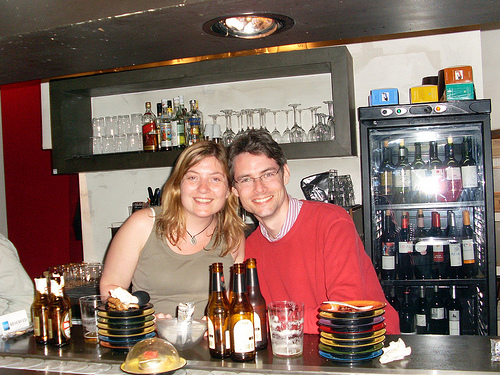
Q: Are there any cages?
A: No, there are no cages.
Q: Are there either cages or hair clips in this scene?
A: No, there are no cages or hair clips.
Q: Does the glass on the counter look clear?
A: Yes, the glass is clear.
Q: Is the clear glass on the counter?
A: Yes, the glass is on the counter.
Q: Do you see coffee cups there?
A: No, there are no coffee cups.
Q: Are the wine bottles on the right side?
A: Yes, the wine bottles are on the right of the image.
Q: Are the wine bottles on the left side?
A: No, the wine bottles are on the right of the image.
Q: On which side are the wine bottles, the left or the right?
A: The wine bottles are on the right of the image.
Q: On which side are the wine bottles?
A: The wine bottles are on the right of the image.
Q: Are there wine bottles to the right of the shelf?
A: Yes, there are wine bottles to the right of the shelf.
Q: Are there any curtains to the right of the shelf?
A: No, there are wine bottles to the right of the shelf.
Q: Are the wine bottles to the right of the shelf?
A: Yes, the wine bottles are to the right of the shelf.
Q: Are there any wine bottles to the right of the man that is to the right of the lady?
A: Yes, there are wine bottles to the right of the man.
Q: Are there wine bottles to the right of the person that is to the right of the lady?
A: Yes, there are wine bottles to the right of the man.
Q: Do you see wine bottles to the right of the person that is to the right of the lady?
A: Yes, there are wine bottles to the right of the man.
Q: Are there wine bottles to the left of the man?
A: No, the wine bottles are to the right of the man.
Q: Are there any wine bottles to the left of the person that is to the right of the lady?
A: No, the wine bottles are to the right of the man.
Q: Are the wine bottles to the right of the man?
A: Yes, the wine bottles are to the right of the man.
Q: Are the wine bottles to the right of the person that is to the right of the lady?
A: Yes, the wine bottles are to the right of the man.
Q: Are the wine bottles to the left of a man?
A: No, the wine bottles are to the right of a man.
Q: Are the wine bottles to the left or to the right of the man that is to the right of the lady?
A: The wine bottles are to the right of the man.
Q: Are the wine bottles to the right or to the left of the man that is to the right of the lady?
A: The wine bottles are to the right of the man.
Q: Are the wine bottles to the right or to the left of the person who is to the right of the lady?
A: The wine bottles are to the right of the man.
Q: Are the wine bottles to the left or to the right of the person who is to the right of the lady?
A: The wine bottles are to the right of the man.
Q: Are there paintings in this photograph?
A: No, there are no paintings.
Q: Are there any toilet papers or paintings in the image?
A: No, there are no paintings or toilet papers.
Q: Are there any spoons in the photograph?
A: Yes, there is a spoon.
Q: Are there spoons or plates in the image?
A: Yes, there is a spoon.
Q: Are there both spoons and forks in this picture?
A: No, there is a spoon but no forks.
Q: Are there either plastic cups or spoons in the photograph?
A: Yes, there is a plastic spoon.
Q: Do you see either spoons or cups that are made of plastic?
A: Yes, the spoon is made of plastic.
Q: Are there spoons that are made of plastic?
A: Yes, there is a spoon that is made of plastic.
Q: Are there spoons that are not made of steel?
A: Yes, there is a spoon that is made of plastic.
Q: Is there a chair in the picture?
A: No, there are no chairs.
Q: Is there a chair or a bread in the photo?
A: No, there are no chairs or breads.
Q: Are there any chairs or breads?
A: No, there are no chairs or breads.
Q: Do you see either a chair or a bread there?
A: No, there are no chairs or breads.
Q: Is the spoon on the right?
A: Yes, the spoon is on the right of the image.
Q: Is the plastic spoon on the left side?
A: No, the spoon is on the right of the image.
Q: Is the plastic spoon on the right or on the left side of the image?
A: The spoon is on the right of the image.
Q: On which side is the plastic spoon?
A: The spoon is on the right of the image.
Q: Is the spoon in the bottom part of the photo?
A: Yes, the spoon is in the bottom of the image.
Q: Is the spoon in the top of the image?
A: No, the spoon is in the bottom of the image.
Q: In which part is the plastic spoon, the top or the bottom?
A: The spoon is in the bottom of the image.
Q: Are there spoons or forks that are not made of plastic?
A: No, there is a spoon but it is made of plastic.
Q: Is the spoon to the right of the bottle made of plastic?
A: Yes, the spoon is made of plastic.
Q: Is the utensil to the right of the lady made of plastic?
A: Yes, the spoon is made of plastic.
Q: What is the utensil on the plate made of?
A: The spoon is made of plastic.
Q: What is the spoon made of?
A: The spoon is made of plastic.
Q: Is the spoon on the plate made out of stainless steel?
A: No, the spoon is made of plastic.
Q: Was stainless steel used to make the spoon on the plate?
A: No, the spoon is made of plastic.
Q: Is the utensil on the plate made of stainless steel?
A: No, the spoon is made of plastic.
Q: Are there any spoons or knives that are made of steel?
A: No, there is a spoon but it is made of plastic.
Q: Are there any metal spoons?
A: No, there is a spoon but it is made of plastic.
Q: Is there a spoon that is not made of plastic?
A: No, there is a spoon but it is made of plastic.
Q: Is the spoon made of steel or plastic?
A: The spoon is made of plastic.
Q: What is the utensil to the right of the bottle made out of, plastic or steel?
A: The spoon is made of plastic.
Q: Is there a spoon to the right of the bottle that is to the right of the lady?
A: Yes, there is a spoon to the right of the bottle.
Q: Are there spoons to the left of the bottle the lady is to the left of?
A: No, the spoon is to the right of the bottle.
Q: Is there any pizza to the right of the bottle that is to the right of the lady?
A: No, there is a spoon to the right of the bottle.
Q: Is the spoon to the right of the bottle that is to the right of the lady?
A: Yes, the spoon is to the right of the bottle.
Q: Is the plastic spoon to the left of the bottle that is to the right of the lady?
A: No, the spoon is to the right of the bottle.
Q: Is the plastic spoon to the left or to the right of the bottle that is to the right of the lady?
A: The spoon is to the right of the bottle.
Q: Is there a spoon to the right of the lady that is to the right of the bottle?
A: Yes, there is a spoon to the right of the lady.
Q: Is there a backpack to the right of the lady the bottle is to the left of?
A: No, there is a spoon to the right of the lady.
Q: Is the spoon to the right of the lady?
A: Yes, the spoon is to the right of the lady.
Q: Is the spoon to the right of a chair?
A: No, the spoon is to the right of the lady.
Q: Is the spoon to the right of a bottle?
A: Yes, the spoon is to the right of a bottle.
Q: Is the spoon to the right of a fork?
A: No, the spoon is to the right of a bottle.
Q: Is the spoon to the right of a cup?
A: No, the spoon is to the right of a bottle.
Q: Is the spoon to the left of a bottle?
A: No, the spoon is to the right of a bottle.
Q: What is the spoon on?
A: The spoon is on the plate.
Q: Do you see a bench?
A: No, there are no benches.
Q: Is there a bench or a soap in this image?
A: No, there are no benches or soaps.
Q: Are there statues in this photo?
A: No, there are no statues.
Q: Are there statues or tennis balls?
A: No, there are no statues or tennis balls.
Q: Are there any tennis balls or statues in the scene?
A: No, there are no statues or tennis balls.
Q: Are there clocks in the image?
A: No, there are no clocks.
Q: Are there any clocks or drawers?
A: No, there are no clocks or drawers.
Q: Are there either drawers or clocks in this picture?
A: No, there are no clocks or drawers.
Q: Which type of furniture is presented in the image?
A: The furniture is a shelf.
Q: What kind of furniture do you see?
A: The furniture is a shelf.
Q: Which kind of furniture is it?
A: The piece of furniture is a shelf.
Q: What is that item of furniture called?
A: This is a shelf.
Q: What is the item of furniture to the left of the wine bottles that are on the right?
A: The piece of furniture is a shelf.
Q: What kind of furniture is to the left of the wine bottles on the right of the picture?
A: The piece of furniture is a shelf.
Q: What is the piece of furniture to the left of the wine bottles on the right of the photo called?
A: The piece of furniture is a shelf.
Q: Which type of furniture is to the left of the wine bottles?
A: The piece of furniture is a shelf.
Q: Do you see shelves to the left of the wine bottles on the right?
A: Yes, there is a shelf to the left of the wine bottles.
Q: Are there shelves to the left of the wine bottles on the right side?
A: Yes, there is a shelf to the left of the wine bottles.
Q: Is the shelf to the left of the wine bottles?
A: Yes, the shelf is to the left of the wine bottles.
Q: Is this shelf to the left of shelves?
A: No, the shelf is to the left of the wine bottles.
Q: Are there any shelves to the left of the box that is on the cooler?
A: Yes, there is a shelf to the left of the box.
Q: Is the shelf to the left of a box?
A: Yes, the shelf is to the left of a box.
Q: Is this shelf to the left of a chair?
A: No, the shelf is to the left of a box.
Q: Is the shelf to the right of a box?
A: No, the shelf is to the left of a box.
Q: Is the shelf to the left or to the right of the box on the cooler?
A: The shelf is to the left of the box.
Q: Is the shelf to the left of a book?
A: No, the shelf is to the left of the box.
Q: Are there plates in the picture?
A: Yes, there is a plate.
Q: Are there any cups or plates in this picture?
A: Yes, there is a plate.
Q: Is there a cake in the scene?
A: No, there are no cakes.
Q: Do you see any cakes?
A: No, there are no cakes.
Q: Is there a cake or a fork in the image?
A: No, there are no cakes or forks.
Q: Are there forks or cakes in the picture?
A: No, there are no cakes or forks.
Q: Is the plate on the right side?
A: Yes, the plate is on the right of the image.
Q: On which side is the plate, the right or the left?
A: The plate is on the right of the image.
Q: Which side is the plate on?
A: The plate is on the right of the image.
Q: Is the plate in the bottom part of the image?
A: Yes, the plate is in the bottom of the image.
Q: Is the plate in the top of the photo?
A: No, the plate is in the bottom of the image.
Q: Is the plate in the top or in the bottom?
A: The plate is in the bottom of the image.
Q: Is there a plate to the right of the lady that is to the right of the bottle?
A: Yes, there is a plate to the right of the lady.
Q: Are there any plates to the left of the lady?
A: No, the plate is to the right of the lady.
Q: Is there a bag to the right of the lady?
A: No, there is a plate to the right of the lady.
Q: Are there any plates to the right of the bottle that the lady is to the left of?
A: Yes, there is a plate to the right of the bottle.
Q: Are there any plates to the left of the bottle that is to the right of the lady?
A: No, the plate is to the right of the bottle.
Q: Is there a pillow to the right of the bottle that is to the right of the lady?
A: No, there is a plate to the right of the bottle.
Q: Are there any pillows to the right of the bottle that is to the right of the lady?
A: No, there is a plate to the right of the bottle.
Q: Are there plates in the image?
A: Yes, there is a plate.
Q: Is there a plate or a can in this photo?
A: Yes, there is a plate.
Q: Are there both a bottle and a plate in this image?
A: Yes, there are both a plate and a bottle.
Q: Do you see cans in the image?
A: No, there are no cans.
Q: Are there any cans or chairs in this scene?
A: No, there are no cans or chairs.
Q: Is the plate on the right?
A: Yes, the plate is on the right of the image.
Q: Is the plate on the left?
A: No, the plate is on the right of the image.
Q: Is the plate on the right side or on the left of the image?
A: The plate is on the right of the image.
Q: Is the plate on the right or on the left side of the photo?
A: The plate is on the right of the image.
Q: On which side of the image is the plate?
A: The plate is on the right of the image.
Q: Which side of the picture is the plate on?
A: The plate is on the right of the image.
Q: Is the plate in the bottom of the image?
A: Yes, the plate is in the bottom of the image.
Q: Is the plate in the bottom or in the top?
A: The plate is in the bottom of the image.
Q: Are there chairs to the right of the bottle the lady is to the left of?
A: No, there is a plate to the right of the bottle.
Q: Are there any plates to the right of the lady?
A: Yes, there is a plate to the right of the lady.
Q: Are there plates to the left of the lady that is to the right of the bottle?
A: No, the plate is to the right of the lady.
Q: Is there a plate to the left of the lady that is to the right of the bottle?
A: No, the plate is to the right of the lady.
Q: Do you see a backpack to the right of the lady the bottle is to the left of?
A: No, there is a plate to the right of the lady.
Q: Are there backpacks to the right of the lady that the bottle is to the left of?
A: No, there is a plate to the right of the lady.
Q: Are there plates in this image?
A: Yes, there is a plate.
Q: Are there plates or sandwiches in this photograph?
A: Yes, there is a plate.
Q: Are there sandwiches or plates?
A: Yes, there is a plate.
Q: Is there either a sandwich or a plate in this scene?
A: Yes, there is a plate.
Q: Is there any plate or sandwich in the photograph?
A: Yes, there is a plate.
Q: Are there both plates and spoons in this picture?
A: Yes, there are both a plate and a spoon.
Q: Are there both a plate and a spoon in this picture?
A: Yes, there are both a plate and a spoon.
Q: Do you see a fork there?
A: No, there are no forks.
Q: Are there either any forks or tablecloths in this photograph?
A: No, there are no forks or tablecloths.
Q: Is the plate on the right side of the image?
A: Yes, the plate is on the right of the image.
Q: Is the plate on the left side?
A: No, the plate is on the right of the image.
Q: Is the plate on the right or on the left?
A: The plate is on the right of the image.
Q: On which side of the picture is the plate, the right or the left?
A: The plate is on the right of the image.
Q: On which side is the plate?
A: The plate is on the right of the image.